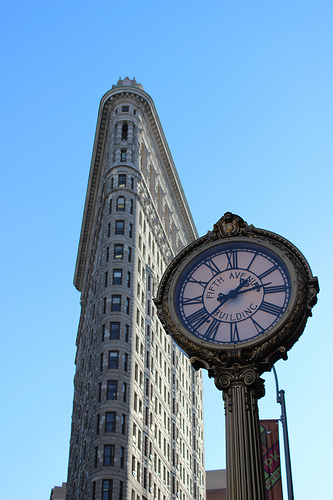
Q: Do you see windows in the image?
A: Yes, there is a window.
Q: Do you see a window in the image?
A: Yes, there is a window.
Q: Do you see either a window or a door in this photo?
A: Yes, there is a window.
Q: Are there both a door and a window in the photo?
A: No, there is a window but no doors.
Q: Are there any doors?
A: No, there are no doors.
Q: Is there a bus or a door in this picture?
A: No, there are no doors or buses.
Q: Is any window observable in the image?
A: Yes, there is a window.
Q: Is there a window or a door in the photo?
A: Yes, there is a window.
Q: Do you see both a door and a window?
A: No, there is a window but no doors.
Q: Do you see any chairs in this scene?
A: No, there are no chairs.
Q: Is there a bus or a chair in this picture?
A: No, there are no chairs or buses.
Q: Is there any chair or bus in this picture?
A: No, there are no chairs or buses.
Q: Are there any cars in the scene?
A: No, there are no cars.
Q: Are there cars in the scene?
A: No, there are no cars.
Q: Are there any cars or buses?
A: No, there are no cars or buses.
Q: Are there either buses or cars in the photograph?
A: No, there are no cars or buses.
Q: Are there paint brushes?
A: No, there are no paint brushes.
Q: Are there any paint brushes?
A: No, there are no paint brushes.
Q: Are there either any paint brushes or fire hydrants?
A: No, there are no paint brushes or fire hydrants.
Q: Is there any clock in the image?
A: Yes, there is a clock.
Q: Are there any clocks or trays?
A: Yes, there is a clock.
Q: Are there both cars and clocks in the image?
A: No, there is a clock but no cars.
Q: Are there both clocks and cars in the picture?
A: No, there is a clock but no cars.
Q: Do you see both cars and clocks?
A: No, there is a clock but no cars.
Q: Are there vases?
A: No, there are no vases.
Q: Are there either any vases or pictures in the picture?
A: No, there are no vases or pictures.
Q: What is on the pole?
A: The clock is on the pole.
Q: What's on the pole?
A: The clock is on the pole.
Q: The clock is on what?
A: The clock is on the pole.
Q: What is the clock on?
A: The clock is on the pole.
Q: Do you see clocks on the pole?
A: Yes, there is a clock on the pole.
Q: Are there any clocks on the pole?
A: Yes, there is a clock on the pole.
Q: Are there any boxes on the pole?
A: No, there is a clock on the pole.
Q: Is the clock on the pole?
A: Yes, the clock is on the pole.